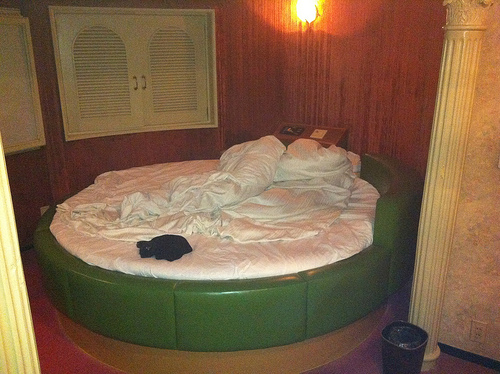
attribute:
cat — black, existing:
[133, 233, 192, 261]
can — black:
[380, 317, 429, 373]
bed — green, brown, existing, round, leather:
[35, 121, 418, 373]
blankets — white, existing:
[49, 137, 382, 283]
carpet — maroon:
[21, 249, 125, 373]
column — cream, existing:
[0, 126, 42, 372]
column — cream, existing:
[404, 0, 489, 362]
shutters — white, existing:
[52, 9, 215, 137]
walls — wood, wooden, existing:
[0, 1, 446, 251]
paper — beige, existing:
[425, 2, 499, 363]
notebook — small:
[310, 127, 328, 140]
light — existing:
[294, 1, 321, 28]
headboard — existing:
[361, 149, 423, 250]